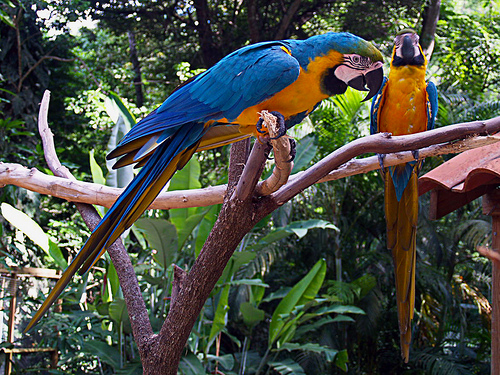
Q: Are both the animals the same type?
A: Yes, all the animals are birds.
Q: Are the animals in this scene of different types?
A: No, all the animals are birds.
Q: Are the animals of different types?
A: No, all the animals are birds.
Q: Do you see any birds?
A: Yes, there is a bird.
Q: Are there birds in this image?
A: Yes, there is a bird.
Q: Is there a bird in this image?
A: Yes, there is a bird.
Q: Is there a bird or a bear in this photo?
A: Yes, there is a bird.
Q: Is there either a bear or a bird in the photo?
A: Yes, there is a bird.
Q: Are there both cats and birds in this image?
A: No, there is a bird but no cats.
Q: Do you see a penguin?
A: No, there are no penguins.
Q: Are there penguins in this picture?
A: No, there are no penguins.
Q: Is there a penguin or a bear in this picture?
A: No, there are no penguins or bears.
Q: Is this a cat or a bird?
A: This is a bird.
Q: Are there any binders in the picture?
A: No, there are no binders.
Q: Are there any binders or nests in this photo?
A: No, there are no binders or nests.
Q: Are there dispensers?
A: No, there are no dispensers.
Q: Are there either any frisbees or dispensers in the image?
A: No, there are no dispensers or frisbees.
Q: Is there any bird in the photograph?
A: Yes, there is a bird.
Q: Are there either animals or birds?
A: Yes, there is a bird.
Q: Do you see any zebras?
A: No, there are no zebras.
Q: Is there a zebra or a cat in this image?
A: No, there are no zebras or cats.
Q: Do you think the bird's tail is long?
A: Yes, the tail is long.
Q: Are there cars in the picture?
A: No, there are no cars.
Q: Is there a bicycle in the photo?
A: No, there are no bicycles.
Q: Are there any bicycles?
A: No, there are no bicycles.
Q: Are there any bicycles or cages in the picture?
A: No, there are no bicycles or cages.